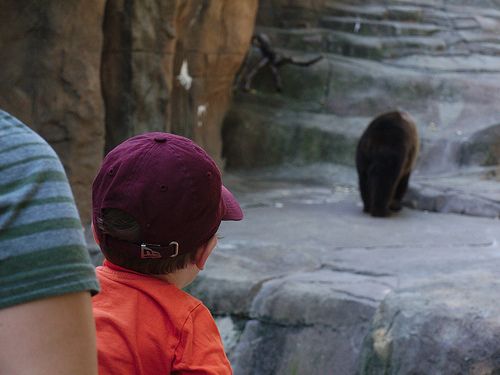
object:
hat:
[89, 132, 244, 259]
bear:
[354, 109, 420, 218]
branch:
[234, 33, 324, 95]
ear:
[195, 236, 219, 271]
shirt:
[92, 260, 234, 374]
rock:
[1, 0, 261, 222]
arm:
[0, 110, 98, 374]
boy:
[91, 131, 245, 375]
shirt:
[1, 108, 103, 309]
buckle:
[140, 241, 179, 259]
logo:
[140, 243, 162, 259]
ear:
[90, 222, 100, 247]